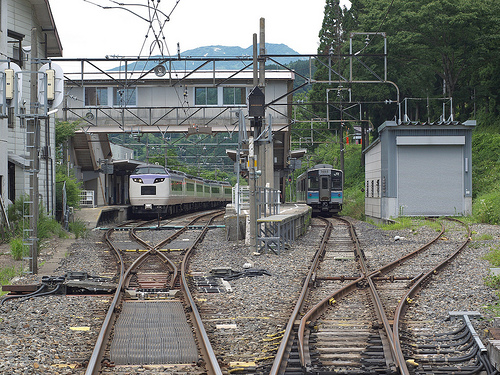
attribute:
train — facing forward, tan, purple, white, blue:
[129, 161, 235, 218]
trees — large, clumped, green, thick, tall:
[305, 0, 499, 121]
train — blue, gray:
[293, 166, 345, 217]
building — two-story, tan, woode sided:
[0, 3, 64, 226]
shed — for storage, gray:
[361, 118, 476, 219]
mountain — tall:
[113, 41, 312, 70]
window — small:
[13, 48, 25, 65]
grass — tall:
[39, 216, 71, 241]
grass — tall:
[11, 237, 25, 260]